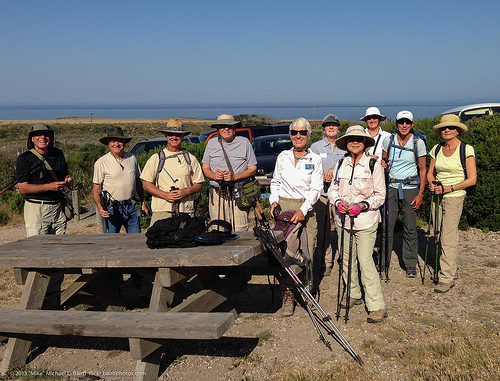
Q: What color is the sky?
A: Blue.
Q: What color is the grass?
A: Green.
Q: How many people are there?
A: Ten.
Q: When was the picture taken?
A: Daytime.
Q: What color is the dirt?
A: Brown.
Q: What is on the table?
A: A bag.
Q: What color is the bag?
A: Black.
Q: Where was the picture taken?
A: At a beach.